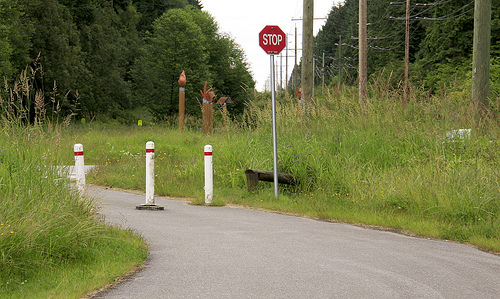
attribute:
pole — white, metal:
[198, 140, 217, 209]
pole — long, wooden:
[467, 0, 491, 136]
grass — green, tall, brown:
[1, 117, 144, 297]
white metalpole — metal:
[71, 142, 88, 202]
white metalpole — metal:
[142, 135, 156, 201]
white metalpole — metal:
[200, 143, 215, 201]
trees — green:
[0, 0, 257, 127]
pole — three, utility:
[301, 0, 312, 110]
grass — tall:
[1, 74, 71, 139]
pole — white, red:
[73, 142, 86, 203]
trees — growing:
[0, 7, 497, 117]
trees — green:
[286, 1, 499, 100]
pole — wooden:
[201, 136, 215, 206]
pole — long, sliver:
[266, 53, 281, 198]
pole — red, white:
[145, 139, 156, 204]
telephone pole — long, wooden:
[352, 0, 372, 111]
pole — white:
[69, 139, 89, 201]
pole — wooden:
[291, 0, 373, 212]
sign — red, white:
[258, 23, 286, 56]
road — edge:
[49, 164, 499, 297]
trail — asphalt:
[47, 161, 496, 298]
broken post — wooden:
[244, 167, 296, 190]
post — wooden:
[462, 3, 496, 52]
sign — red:
[255, 22, 290, 57]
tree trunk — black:
[244, 168, 297, 190]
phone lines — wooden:
[273, 8, 301, 30]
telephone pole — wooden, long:
[403, 0, 410, 103]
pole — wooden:
[293, 28, 297, 93]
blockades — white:
[67, 135, 217, 208]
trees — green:
[0, 4, 254, 111]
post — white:
[70, 140, 88, 210]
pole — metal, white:
[199, 141, 212, 203]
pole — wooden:
[465, 5, 495, 142]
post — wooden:
[299, 7, 318, 123]